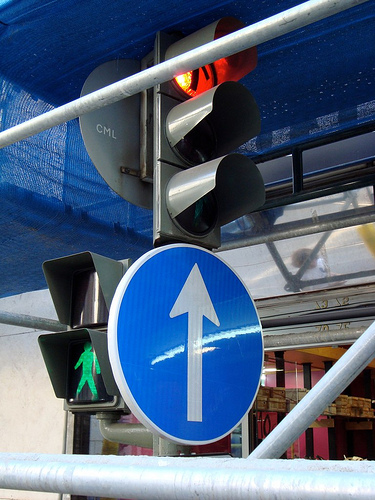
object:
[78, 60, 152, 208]
sign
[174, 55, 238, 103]
red light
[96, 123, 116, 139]
cml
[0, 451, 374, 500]
metal pole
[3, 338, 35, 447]
wall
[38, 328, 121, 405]
light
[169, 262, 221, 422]
arrow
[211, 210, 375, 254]
pole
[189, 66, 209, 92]
arrow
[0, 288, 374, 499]
street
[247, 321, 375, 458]
pole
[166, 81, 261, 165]
light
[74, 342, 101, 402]
crossing ligth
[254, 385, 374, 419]
wood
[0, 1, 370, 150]
bar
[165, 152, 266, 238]
light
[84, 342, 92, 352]
head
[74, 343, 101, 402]
green man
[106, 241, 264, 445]
sign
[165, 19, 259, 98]
light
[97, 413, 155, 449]
pole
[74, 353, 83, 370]
arm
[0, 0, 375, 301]
canopy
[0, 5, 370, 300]
tarp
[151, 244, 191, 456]
pole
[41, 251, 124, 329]
light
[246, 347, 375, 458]
store